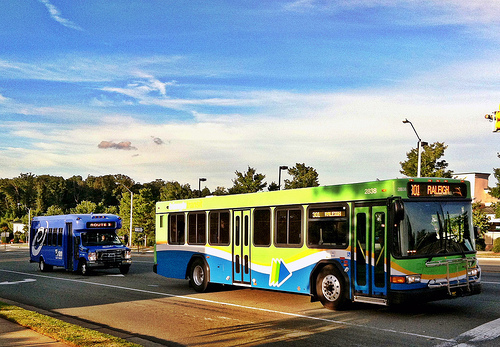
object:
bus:
[25, 215, 142, 279]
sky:
[1, 0, 499, 191]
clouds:
[98, 139, 135, 154]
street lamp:
[400, 116, 422, 177]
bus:
[151, 180, 479, 310]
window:
[388, 195, 473, 255]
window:
[168, 210, 353, 250]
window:
[36, 227, 63, 244]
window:
[82, 227, 118, 244]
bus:
[140, 0, 482, 132]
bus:
[10, 173, 498, 318]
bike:
[427, 257, 481, 298]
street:
[0, 245, 497, 345]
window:
[275, 206, 287, 246]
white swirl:
[155, 241, 351, 279]